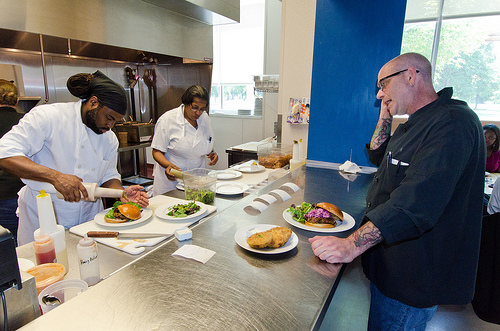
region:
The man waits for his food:
[239, 48, 482, 313]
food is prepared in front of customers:
[59, 53, 257, 292]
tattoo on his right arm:
[370, 106, 395, 150]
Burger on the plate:
[290, 200, 360, 238]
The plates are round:
[228, 200, 355, 275]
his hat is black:
[88, 78, 130, 102]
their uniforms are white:
[25, 112, 210, 220]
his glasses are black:
[361, 65, 419, 100]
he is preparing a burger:
[83, 186, 147, 241]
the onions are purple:
[310, 207, 335, 217]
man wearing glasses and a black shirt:
[363, 53, 470, 298]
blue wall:
[330, 3, 365, 152]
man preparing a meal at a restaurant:
[58, 75, 144, 224]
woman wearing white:
[155, 88, 215, 183]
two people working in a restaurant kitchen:
[18, 74, 218, 189]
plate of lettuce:
[168, 201, 202, 216]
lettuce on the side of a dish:
[289, 196, 309, 225]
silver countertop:
[138, 262, 303, 324]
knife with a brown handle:
[87, 229, 170, 239]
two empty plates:
[214, 170, 251, 195]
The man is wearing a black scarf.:
[61, 71, 129, 134]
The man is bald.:
[367, 49, 440, 116]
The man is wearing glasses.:
[370, 47, 439, 113]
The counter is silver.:
[120, 281, 250, 328]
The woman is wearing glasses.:
[181, 86, 210, 119]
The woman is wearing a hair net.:
[178, 80, 212, 126]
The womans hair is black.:
[180, 80, 213, 122]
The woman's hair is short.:
[178, 81, 215, 125]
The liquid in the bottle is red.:
[34, 229, 56, 266]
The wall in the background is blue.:
[323, 5, 372, 100]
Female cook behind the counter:
[147, 81, 222, 197]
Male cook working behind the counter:
[1, 64, 151, 245]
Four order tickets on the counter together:
[241, 178, 301, 217]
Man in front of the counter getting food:
[305, 49, 489, 329]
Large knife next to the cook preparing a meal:
[83, 224, 175, 244]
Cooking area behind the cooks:
[1, 0, 218, 244]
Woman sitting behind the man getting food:
[478, 119, 499, 175]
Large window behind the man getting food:
[382, 1, 496, 125]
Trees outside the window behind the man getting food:
[399, 0, 499, 112]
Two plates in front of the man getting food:
[232, 196, 359, 261]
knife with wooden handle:
[78, 220, 203, 250]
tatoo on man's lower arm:
[341, 229, 413, 249]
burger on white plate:
[295, 198, 354, 225]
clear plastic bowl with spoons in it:
[30, 280, 94, 314]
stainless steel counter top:
[141, 269, 214, 329]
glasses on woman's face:
[191, 98, 216, 116]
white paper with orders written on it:
[245, 187, 307, 209]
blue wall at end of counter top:
[322, 55, 349, 137]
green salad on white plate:
[176, 199, 210, 224]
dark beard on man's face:
[83, 104, 114, 139]